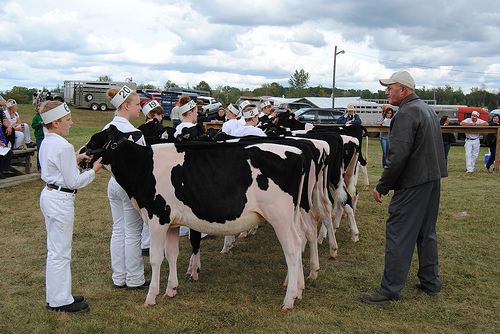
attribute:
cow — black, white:
[69, 126, 325, 307]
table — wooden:
[366, 120, 484, 135]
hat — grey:
[374, 61, 417, 89]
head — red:
[104, 69, 150, 126]